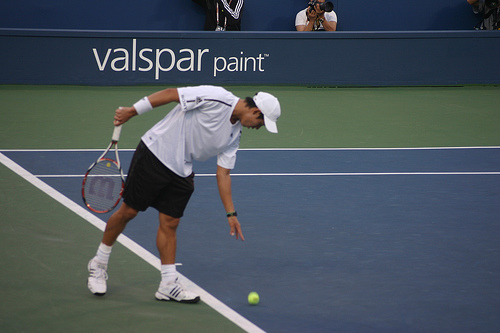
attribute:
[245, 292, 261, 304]
ball — yellow, small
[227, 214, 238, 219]
watch — black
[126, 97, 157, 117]
wristband — white, green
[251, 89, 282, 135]
cap — white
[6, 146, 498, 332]
lines — white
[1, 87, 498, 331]
pavement — green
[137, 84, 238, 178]
shirt — black, white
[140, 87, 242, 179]
shirt — white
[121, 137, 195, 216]
shorts — black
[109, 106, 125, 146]
grip — white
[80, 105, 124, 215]
racket — red, white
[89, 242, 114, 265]
sock — white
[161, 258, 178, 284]
sock — white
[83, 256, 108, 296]
shoe — white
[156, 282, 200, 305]
shoe — white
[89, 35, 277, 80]
sign — white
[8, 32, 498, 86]
wall — blue